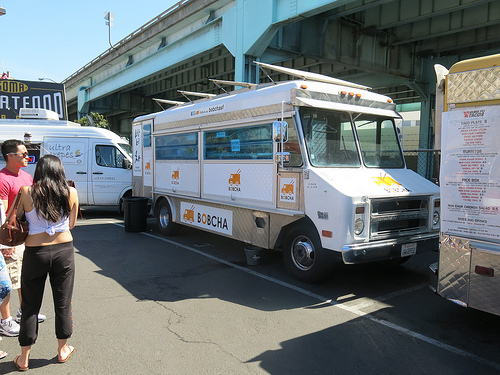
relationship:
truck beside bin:
[131, 59, 440, 284] [122, 196, 155, 233]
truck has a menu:
[131, 59, 440, 284] [441, 107, 497, 243]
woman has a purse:
[13, 153, 74, 374] [3, 187, 29, 247]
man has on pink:
[2, 140, 46, 337] [2, 169, 33, 213]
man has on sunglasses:
[2, 140, 46, 337] [6, 152, 28, 160]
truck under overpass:
[131, 59, 440, 284] [56, 1, 497, 180]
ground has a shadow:
[1, 215, 498, 375] [243, 286, 499, 374]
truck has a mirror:
[131, 59, 440, 282] [272, 120, 287, 142]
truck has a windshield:
[131, 59, 440, 282] [296, 105, 406, 168]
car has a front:
[1, 107, 134, 217] [93, 127, 131, 213]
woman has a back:
[13, 153, 74, 374] [22, 189, 73, 245]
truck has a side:
[131, 59, 440, 282] [130, 80, 273, 250]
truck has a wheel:
[131, 59, 440, 282] [278, 219, 335, 284]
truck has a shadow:
[131, 59, 440, 282] [243, 286, 499, 374]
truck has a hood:
[131, 59, 440, 282] [311, 166, 438, 197]